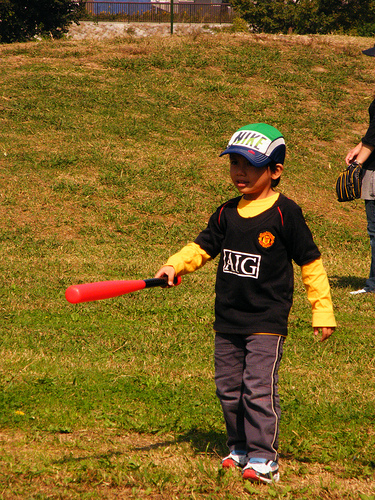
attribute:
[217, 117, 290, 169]
hat — green,white,black, nike, green,white,blue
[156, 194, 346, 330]
shirt — black, yellow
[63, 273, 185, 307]
bat — red, black, plastic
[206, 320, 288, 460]
pants — grey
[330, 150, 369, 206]
mit — black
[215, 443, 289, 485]
shoes — white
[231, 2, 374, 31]
trees — green, brown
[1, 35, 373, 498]
lawn — green, brown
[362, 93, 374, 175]
jacket — black